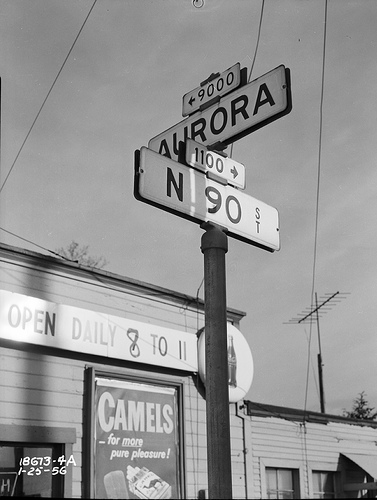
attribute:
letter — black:
[160, 166, 183, 201]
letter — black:
[200, 184, 222, 213]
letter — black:
[222, 193, 241, 223]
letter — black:
[254, 207, 261, 217]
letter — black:
[253, 221, 261, 231]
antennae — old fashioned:
[274, 289, 350, 419]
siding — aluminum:
[0, 401, 83, 423]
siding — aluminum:
[0, 355, 85, 380]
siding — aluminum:
[0, 384, 83, 408]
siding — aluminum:
[0, 267, 205, 330]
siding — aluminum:
[183, 458, 207, 472]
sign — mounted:
[5, 287, 201, 378]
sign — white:
[2, 290, 199, 370]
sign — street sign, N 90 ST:
[114, 113, 315, 252]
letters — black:
[7, 302, 187, 361]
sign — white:
[2, 289, 255, 403]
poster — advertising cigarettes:
[63, 360, 207, 494]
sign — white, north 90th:
[135, 147, 284, 252]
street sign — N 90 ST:
[132, 148, 282, 253]